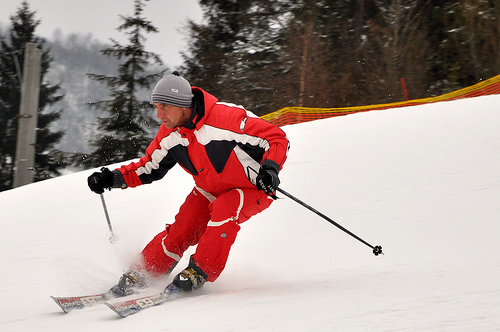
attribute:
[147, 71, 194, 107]
hat — grey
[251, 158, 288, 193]
glove — black, grey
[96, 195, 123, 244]
ski pole — black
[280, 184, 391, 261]
ski pole — black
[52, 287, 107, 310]
ski — red, white, blue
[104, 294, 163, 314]
ski — blue, white, red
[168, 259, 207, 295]
boot — black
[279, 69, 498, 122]
fence — orange, yellow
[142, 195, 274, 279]
pants — red, white, black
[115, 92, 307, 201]
jacket — red, white